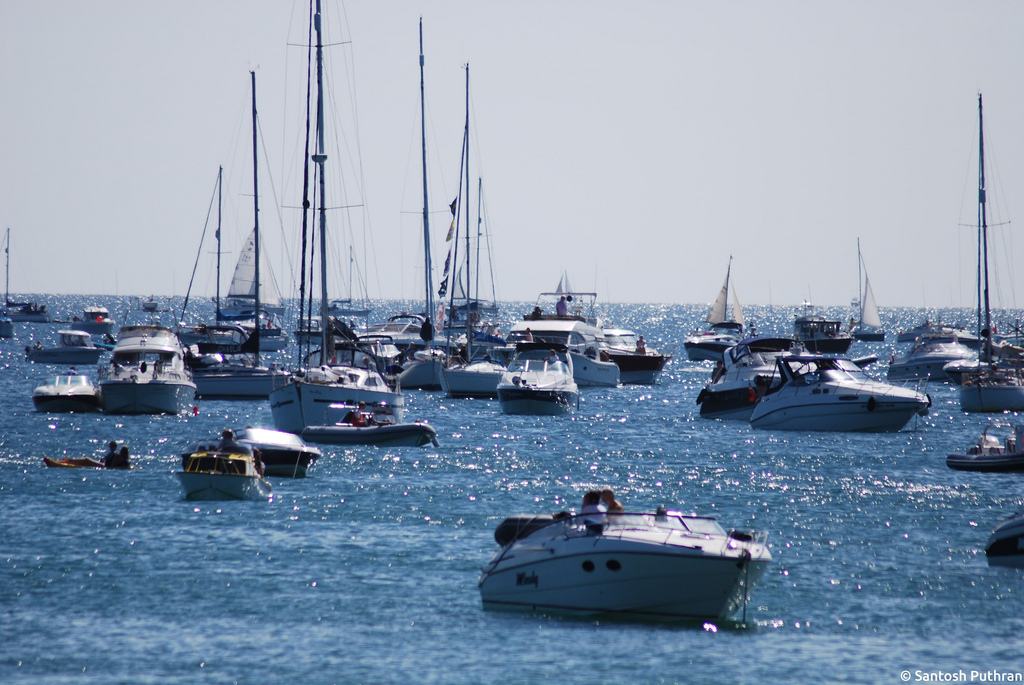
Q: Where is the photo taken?
A: Ocean.